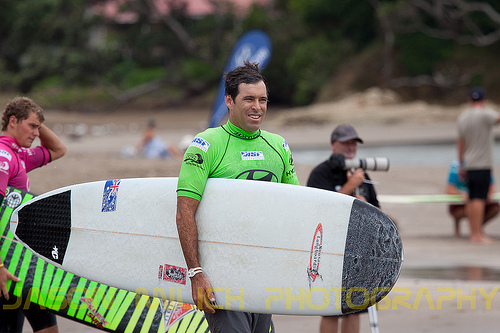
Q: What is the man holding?
A: A surfboard.